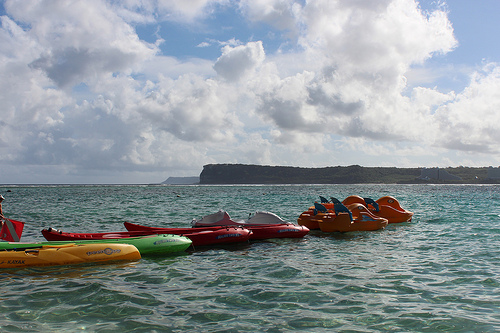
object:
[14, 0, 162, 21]
clouds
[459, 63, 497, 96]
clouds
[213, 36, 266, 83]
cloud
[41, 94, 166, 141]
cloud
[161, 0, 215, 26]
cloud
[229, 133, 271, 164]
cloud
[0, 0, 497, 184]
sky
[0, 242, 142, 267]
tube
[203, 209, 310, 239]
tube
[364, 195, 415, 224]
paddle boats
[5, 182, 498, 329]
water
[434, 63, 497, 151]
cloud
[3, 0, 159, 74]
cloud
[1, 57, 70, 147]
cloud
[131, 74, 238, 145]
cloud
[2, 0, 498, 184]
blue sky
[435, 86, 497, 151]
white clouds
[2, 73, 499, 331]
background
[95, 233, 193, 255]
colored raft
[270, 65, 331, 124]
clouds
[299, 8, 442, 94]
clouds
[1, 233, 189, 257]
tube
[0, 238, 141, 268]
yellow raft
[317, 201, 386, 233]
raft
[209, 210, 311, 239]
raft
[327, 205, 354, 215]
seats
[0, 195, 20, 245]
person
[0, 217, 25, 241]
material